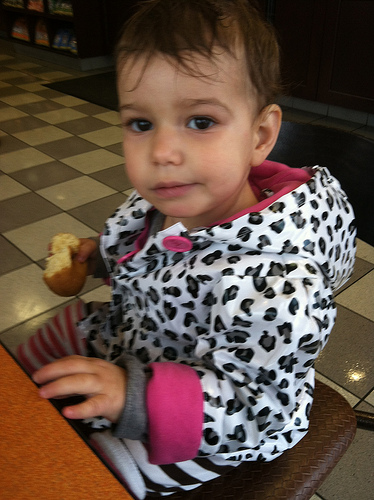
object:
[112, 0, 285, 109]
brown hair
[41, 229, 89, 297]
snack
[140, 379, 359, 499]
chair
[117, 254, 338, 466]
sleeves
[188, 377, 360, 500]
seat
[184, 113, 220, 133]
eye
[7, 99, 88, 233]
tiled floor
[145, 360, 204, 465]
pink cuffs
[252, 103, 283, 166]
ear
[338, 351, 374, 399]
light tiles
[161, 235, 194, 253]
pink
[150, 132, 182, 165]
nose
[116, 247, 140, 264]
button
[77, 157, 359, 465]
coat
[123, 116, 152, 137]
brown eyes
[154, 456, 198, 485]
stripe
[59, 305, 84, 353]
stripe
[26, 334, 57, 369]
stripe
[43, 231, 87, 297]
donut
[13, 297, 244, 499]
pants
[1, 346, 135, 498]
table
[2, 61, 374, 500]
tiles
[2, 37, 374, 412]
floor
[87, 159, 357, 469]
jacket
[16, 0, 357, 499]
baby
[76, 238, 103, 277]
hand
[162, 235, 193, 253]
button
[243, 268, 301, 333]
leapord spots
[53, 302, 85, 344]
stripes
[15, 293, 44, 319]
light